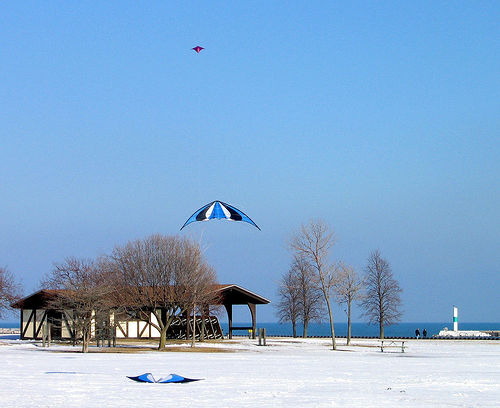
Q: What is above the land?
A: A blue sky.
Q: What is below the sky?
A: A white snowy park.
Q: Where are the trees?
A: By the beach.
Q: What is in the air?
A: Kites.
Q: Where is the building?
A: Behind the trees.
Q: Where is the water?
A: Beyond the fence.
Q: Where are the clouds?
A: Gone away.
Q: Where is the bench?
A: Next to the trees.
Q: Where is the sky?
A: Above the ocean.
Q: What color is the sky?
A: Blue.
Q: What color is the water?
A: Dark blue.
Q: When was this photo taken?
A: Daylight hours.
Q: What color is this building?
A: Tan and brown.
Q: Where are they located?
A: By the sea.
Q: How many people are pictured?
A: Two.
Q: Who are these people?
A: Pedestrians.